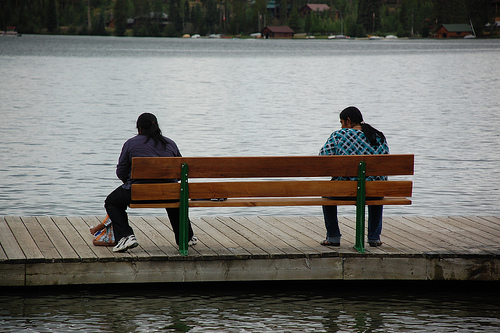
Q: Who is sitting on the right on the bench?
A: A woman.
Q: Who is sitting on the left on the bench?
A: A woman with a navy shirt.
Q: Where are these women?
A: Pier.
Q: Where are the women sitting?
A: On a bench.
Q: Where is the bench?
A: On a wooden walkway.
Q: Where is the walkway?
A: On a lake.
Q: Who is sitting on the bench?
A: Two women.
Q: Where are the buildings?
A: On the other side of the lake.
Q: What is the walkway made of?
A: Wood.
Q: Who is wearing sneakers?
A: Person on left.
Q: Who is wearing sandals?
A: Woman on right.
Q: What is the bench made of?
A: Wood and metal.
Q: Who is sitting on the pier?
A: A small child.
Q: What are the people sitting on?
A: Bench.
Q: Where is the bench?
A: On a pier.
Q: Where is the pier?
A: On the water.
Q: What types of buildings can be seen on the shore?
A: Houses.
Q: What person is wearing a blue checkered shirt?
A: Woman on the right.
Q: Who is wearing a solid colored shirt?
A: Person on the left.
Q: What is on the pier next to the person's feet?
A: Bag.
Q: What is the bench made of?
A: Wood.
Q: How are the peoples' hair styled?
A: Pony tail.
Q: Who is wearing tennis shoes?
A: Person on left.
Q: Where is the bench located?
A: On the dock.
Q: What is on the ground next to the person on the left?
A: Bags.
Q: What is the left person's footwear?
A: Sneakers.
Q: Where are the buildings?
A: On the other side of the lake.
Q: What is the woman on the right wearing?
A: A blue plaid shirt.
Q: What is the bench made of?
A: Wood.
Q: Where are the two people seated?
A: On a bench.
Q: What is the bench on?
A: A dock.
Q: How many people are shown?
A: Two.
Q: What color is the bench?
A: Brown and green.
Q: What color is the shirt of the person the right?
A: Blue.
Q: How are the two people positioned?
A: Sitting.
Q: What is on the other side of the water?
A: A house, boats, and trees.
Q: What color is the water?
A: Grey.